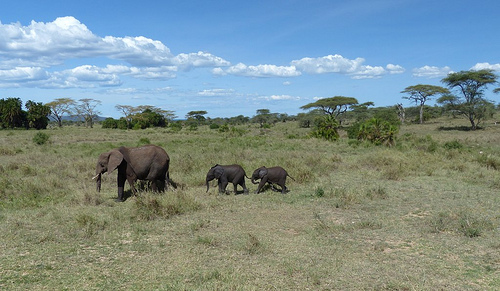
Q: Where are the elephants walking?
A: A green field.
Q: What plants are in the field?
A: Trees.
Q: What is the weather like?
A: Partially cloudy.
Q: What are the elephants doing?
A: Walking.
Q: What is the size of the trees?
A: Large.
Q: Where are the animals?
A: On the ground.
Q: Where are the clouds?
A: In the sky.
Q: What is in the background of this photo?
A: Short bushes.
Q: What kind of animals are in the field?
A: Elephants.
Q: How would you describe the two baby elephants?
A: They are small.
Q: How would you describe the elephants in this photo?
A: They are gray.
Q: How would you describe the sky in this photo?
A: The sky is clear.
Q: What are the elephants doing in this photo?
A: Walking.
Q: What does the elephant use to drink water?
A: The trunk.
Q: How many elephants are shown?
A: Three.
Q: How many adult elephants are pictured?
A: One.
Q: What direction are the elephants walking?
A: Left.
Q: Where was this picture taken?
A: In the wild.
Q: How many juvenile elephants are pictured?
A: Two.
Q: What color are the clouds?
A: White.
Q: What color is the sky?
A: Blue.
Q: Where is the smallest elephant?
A: On the right.